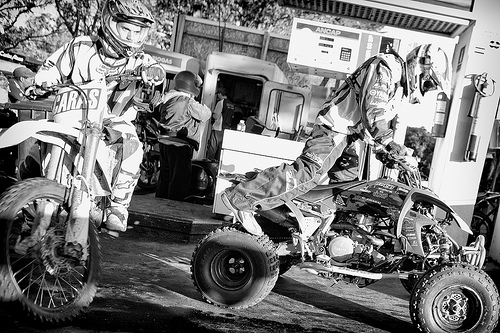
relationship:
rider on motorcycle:
[235, 38, 446, 218] [218, 175, 499, 331]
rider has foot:
[235, 38, 446, 218] [223, 190, 269, 237]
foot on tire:
[223, 190, 269, 237] [191, 223, 280, 310]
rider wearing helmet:
[235, 38, 446, 218] [403, 43, 454, 105]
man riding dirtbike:
[38, 1, 164, 134] [6, 90, 120, 332]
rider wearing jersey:
[235, 38, 446, 218] [324, 55, 405, 139]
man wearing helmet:
[235, 38, 446, 218] [403, 43, 454, 105]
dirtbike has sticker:
[6, 90, 120, 332] [49, 92, 102, 112]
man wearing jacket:
[38, 1, 164, 134] [53, 41, 150, 110]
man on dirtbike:
[38, 1, 164, 134] [6, 90, 120, 332]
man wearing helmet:
[38, 1, 164, 134] [98, 1, 155, 57]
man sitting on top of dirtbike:
[38, 1, 164, 134] [6, 90, 120, 332]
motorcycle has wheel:
[218, 175, 499, 331] [191, 223, 280, 310]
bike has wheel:
[6, 90, 120, 332] [1, 179, 103, 322]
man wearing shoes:
[38, 1, 164, 134] [103, 201, 130, 233]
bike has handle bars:
[6, 90, 120, 332] [20, 77, 168, 97]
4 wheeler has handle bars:
[218, 175, 499, 331] [382, 146, 421, 168]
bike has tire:
[6, 90, 120, 332] [1, 179, 103, 322]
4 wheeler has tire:
[218, 175, 499, 331] [412, 259, 500, 324]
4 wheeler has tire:
[218, 175, 499, 331] [191, 223, 280, 310]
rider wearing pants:
[235, 38, 446, 218] [227, 130, 354, 209]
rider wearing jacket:
[235, 38, 446, 218] [324, 55, 405, 139]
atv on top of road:
[218, 175, 499, 331] [101, 234, 194, 326]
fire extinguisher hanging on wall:
[433, 90, 452, 144] [437, 34, 496, 204]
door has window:
[261, 79, 314, 138] [270, 87, 301, 131]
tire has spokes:
[1, 179, 103, 322] [17, 267, 58, 291]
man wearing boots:
[38, 1, 164, 134] [102, 180, 134, 236]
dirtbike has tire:
[6, 90, 120, 332] [1, 179, 103, 322]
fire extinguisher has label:
[433, 90, 452, 144] [434, 99, 450, 112]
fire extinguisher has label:
[433, 90, 452, 144] [433, 112, 447, 126]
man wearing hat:
[4, 65, 36, 101] [13, 67, 39, 85]